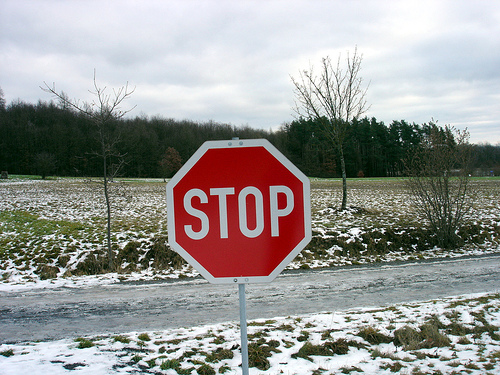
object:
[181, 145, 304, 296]
sign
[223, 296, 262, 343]
pole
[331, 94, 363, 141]
tree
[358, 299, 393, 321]
snow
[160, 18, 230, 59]
sky